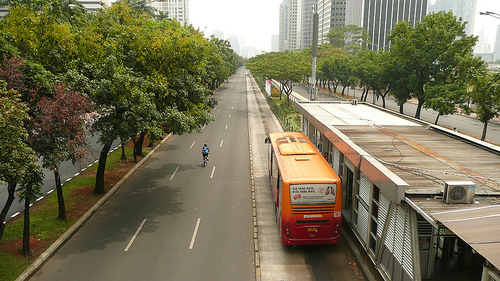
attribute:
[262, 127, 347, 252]
bus — red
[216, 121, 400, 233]
bus — orange 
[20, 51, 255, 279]
roadway — three lane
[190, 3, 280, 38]
sky — cloudy , hazy 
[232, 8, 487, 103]
trees — row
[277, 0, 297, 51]
building — tall 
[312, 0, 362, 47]
building — tall 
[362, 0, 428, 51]
building — tall 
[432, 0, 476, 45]
building — tall 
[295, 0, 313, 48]
building — tall 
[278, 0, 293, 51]
building — tall 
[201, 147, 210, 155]
blue riding — blue 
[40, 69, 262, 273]
street — three lanes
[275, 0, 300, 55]
building — tall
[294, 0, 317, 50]
building — tall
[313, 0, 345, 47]
building — tall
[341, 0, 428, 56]
building — tall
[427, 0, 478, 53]
building — tall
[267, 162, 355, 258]
bus — red , orange 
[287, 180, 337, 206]
advertisement — white 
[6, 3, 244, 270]
trees — Tall 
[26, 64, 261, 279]
highway — green , paved , three lane 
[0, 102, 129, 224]
highway — green 